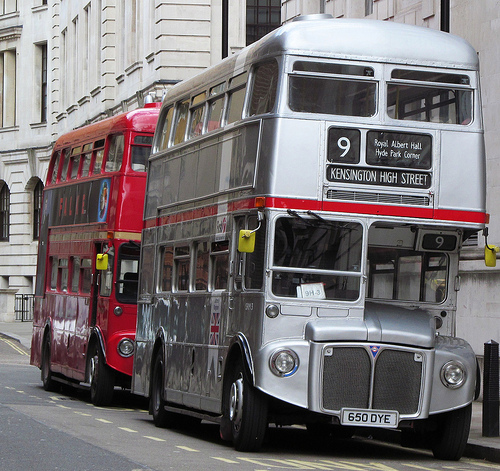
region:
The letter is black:
[368, 410, 376, 426]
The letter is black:
[372, 406, 382, 421]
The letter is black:
[380, 406, 390, 423]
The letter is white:
[325, 165, 335, 180]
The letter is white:
[332, 165, 338, 180]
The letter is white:
[337, 165, 346, 182]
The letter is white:
[343, 164, 350, 181]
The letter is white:
[367, 168, 378, 184]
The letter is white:
[378, 166, 387, 185]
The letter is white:
[399, 168, 409, 187]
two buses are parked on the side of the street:
[23, 10, 491, 463]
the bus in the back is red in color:
[27, 85, 159, 410]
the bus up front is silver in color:
[129, 7, 480, 460]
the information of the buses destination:
[322, 123, 443, 194]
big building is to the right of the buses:
[1, 3, 498, 464]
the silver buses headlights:
[266, 348, 469, 394]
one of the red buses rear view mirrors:
[91, 247, 112, 275]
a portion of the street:
[3, 347, 404, 468]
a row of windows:
[143, 238, 264, 293]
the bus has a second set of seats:
[38, 103, 155, 230]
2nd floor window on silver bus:
[152, 106, 176, 152]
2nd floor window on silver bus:
[168, 104, 188, 144]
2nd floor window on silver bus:
[184, 102, 209, 139]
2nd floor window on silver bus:
[203, 94, 229, 129]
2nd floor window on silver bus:
[223, 83, 248, 123]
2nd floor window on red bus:
[45, 150, 59, 187]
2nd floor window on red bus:
[57, 147, 71, 181]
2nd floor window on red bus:
[67, 155, 83, 179]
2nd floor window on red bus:
[79, 149, 93, 177]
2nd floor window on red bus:
[89, 148, 103, 173]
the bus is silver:
[283, 139, 305, 165]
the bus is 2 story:
[169, 119, 221, 298]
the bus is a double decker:
[56, 159, 80, 324]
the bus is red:
[96, 304, 108, 324]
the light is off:
[276, 353, 291, 370]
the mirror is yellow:
[96, 255, 106, 269]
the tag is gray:
[346, 410, 396, 425]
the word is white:
[335, 167, 372, 181]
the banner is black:
[58, 186, 78, 193]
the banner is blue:
[97, 180, 112, 190]